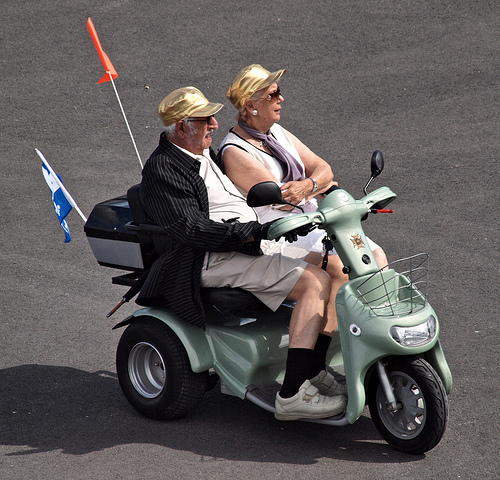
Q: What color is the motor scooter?
A: Green.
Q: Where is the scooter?
A: On road.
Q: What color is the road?
A: Gray.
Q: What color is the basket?
A: Silver.